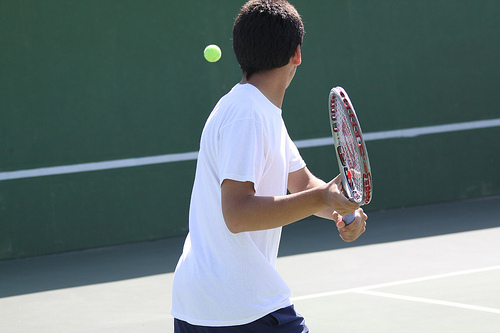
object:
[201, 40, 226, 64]
tennis ball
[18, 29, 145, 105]
air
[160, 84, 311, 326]
t shirt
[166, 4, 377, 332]
person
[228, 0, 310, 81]
head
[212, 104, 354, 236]
arm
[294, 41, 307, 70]
ear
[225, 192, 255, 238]
elbow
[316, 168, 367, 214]
hands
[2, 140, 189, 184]
line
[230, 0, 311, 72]
hair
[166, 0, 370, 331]
man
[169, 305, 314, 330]
shorts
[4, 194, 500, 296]
shadow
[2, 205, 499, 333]
ground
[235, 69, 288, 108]
neck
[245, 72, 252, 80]
hair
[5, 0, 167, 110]
wall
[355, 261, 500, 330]
lines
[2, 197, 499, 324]
court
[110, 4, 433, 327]
tennis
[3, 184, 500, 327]
tennis field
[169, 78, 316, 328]
tee shirt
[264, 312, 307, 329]
pocket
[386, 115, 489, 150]
stripe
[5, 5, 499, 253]
background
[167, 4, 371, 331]
tennis player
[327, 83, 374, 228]
racket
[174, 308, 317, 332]
blue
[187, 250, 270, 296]
white